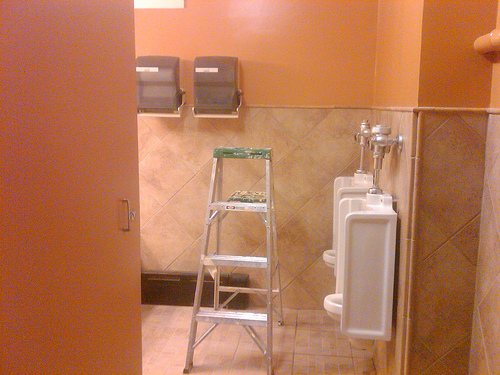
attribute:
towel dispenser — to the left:
[135, 55, 186, 119]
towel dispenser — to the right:
[193, 55, 243, 118]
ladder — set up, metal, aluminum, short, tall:
[183, 147, 284, 374]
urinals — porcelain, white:
[323, 119, 405, 342]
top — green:
[214, 147, 273, 160]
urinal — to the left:
[322, 119, 378, 278]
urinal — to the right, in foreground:
[323, 123, 404, 343]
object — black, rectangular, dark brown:
[141, 269, 250, 311]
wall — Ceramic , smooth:
[134, 0, 500, 375]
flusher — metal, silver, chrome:
[354, 120, 372, 146]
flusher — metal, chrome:
[369, 123, 397, 156]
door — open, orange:
[0, 0, 142, 374]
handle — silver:
[122, 199, 131, 232]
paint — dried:
[233, 187, 268, 201]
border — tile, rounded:
[181, 106, 499, 114]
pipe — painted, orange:
[473, 28, 500, 56]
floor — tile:
[142, 303, 376, 374]